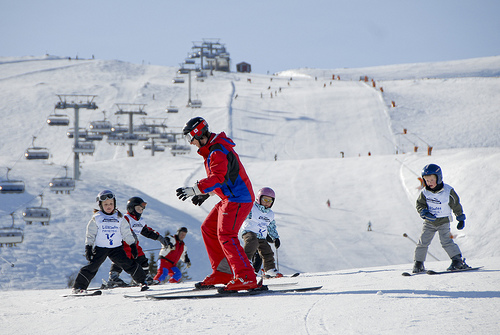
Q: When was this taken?
A: Daytime.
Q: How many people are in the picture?
A: Six.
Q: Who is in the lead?
A: The instructor.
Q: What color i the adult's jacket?
A: Red and blue.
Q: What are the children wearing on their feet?
A: Snow skis.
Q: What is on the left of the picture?
A: Ski lift.